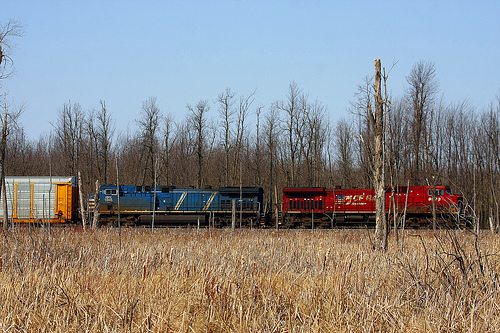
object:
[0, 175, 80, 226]
car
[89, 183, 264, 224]
car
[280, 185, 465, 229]
car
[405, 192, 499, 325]
bush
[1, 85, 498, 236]
trees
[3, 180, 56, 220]
doors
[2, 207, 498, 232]
fence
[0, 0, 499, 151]
sky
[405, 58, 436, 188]
tree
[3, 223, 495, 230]
tracks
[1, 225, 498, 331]
grass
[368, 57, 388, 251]
tree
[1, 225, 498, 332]
field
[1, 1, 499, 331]
photograph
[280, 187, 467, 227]
engine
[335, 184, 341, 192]
smoke stack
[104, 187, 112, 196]
window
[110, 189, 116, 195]
window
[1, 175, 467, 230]
locomotives